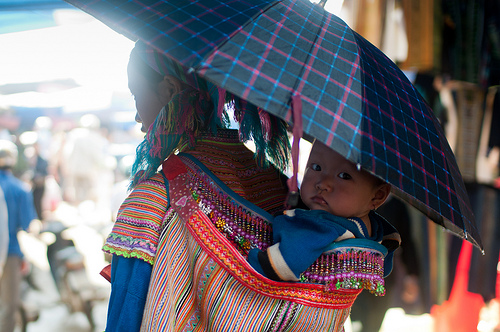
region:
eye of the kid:
[328, 161, 361, 191]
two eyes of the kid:
[294, 153, 361, 200]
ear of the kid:
[358, 175, 396, 220]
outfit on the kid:
[246, 213, 343, 290]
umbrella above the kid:
[276, 61, 395, 138]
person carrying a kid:
[56, 20, 305, 260]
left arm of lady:
[76, 178, 190, 314]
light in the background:
[0, 128, 113, 230]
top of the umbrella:
[177, 17, 375, 103]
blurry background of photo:
[378, 8, 478, 60]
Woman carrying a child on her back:
[102, 38, 401, 330]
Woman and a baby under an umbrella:
[61, 0, 483, 330]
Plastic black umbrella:
[67, 0, 484, 256]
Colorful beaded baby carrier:
[139, 152, 386, 330]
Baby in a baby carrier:
[140, 135, 390, 330]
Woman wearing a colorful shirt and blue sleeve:
[102, 21, 300, 328]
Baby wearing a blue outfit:
[245, 134, 403, 286]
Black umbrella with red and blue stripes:
[62, 0, 484, 254]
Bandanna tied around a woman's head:
[127, 40, 287, 185]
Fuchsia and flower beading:
[189, 162, 386, 296]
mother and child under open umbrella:
[21, 6, 488, 294]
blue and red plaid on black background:
[80, 5, 485, 255]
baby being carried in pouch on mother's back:
[140, 125, 391, 325]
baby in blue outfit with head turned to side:
[255, 105, 390, 290]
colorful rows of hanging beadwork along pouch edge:
[160, 150, 385, 300]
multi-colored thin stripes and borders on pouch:
[140, 205, 360, 328]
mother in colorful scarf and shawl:
[100, 30, 295, 260]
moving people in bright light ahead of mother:
[1, 5, 143, 326]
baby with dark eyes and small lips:
[291, 130, 387, 210]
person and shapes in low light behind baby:
[340, 5, 495, 330]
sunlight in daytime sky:
[1, 0, 348, 112]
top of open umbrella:
[63, 2, 479, 257]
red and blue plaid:
[127, 3, 467, 219]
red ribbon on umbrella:
[287, 94, 304, 191]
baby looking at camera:
[303, 140, 384, 213]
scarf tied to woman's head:
[127, 43, 285, 176]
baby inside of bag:
[149, 141, 390, 330]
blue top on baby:
[261, 207, 398, 281]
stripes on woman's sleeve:
[103, 173, 165, 260]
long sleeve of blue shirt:
[106, 253, 151, 330]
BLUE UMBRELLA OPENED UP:
[177, 32, 494, 191]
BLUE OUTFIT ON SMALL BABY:
[264, 176, 398, 306]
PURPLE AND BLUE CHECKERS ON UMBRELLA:
[284, 61, 372, 123]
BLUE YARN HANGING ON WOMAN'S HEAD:
[77, 101, 223, 199]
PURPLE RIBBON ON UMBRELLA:
[272, 76, 325, 215]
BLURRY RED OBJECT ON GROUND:
[398, 227, 493, 301]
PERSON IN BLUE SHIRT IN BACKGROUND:
[5, 79, 33, 271]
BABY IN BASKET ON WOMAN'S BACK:
[187, 126, 417, 329]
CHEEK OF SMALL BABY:
[316, 189, 369, 223]